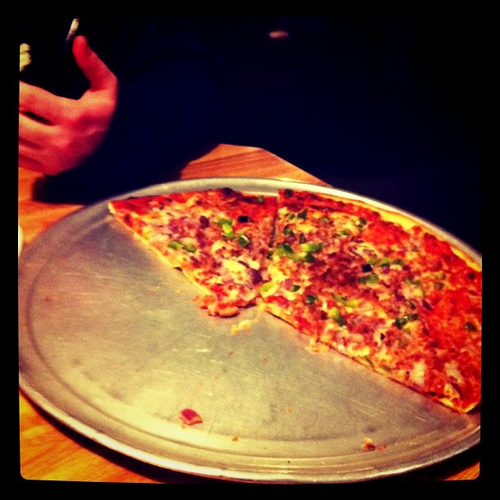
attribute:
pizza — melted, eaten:
[98, 174, 485, 419]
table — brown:
[16, 140, 337, 248]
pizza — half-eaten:
[175, 202, 397, 323]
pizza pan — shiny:
[18, 175, 488, 482]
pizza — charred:
[107, 189, 279, 326]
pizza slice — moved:
[101, 185, 276, 318]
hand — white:
[19, 34, 119, 171]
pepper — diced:
[167, 238, 204, 255]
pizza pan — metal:
[20, 100, 480, 485]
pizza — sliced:
[110, 189, 275, 316]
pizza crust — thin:
[103, 187, 280, 217]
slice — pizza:
[101, 186, 277, 319]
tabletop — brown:
[16, 144, 481, 482]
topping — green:
[216, 219, 246, 246]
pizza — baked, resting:
[16, 162, 496, 487]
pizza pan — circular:
[150, 169, 470, 410]